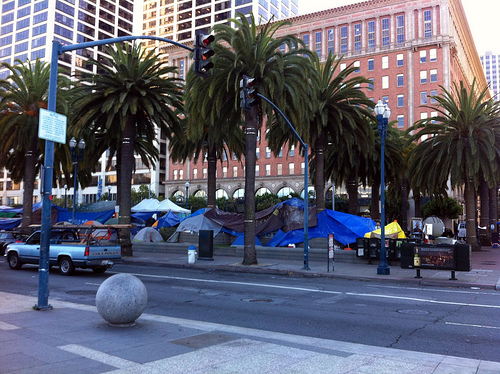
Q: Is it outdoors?
A: Yes, it is outdoors.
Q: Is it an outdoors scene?
A: Yes, it is outdoors.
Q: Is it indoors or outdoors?
A: It is outdoors.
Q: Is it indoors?
A: No, it is outdoors.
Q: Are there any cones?
A: No, there are no cones.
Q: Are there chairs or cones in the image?
A: No, there are no cones or chairs.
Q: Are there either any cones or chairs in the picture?
A: No, there are no cones or chairs.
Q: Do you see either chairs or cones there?
A: No, there are no cones or chairs.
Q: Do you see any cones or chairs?
A: No, there are no cones or chairs.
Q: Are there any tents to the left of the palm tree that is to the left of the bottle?
A: Yes, there are tents to the left of the palm tree.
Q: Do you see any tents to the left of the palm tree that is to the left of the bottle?
A: Yes, there are tents to the left of the palm tree.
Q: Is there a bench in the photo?
A: No, there are no benches.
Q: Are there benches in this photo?
A: No, there are no benches.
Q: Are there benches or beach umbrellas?
A: No, there are no benches or beach umbrellas.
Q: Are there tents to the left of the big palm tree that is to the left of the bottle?
A: Yes, there are tents to the left of the palm tree.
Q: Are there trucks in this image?
A: Yes, there is a truck.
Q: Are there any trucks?
A: Yes, there is a truck.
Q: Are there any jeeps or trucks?
A: Yes, there is a truck.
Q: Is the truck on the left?
A: Yes, the truck is on the left of the image.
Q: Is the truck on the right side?
A: No, the truck is on the left of the image.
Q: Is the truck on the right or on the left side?
A: The truck is on the left of the image.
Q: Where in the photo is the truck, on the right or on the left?
A: The truck is on the left of the image.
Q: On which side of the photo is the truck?
A: The truck is on the left of the image.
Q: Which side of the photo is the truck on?
A: The truck is on the left of the image.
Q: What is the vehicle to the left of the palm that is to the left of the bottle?
A: The vehicle is a truck.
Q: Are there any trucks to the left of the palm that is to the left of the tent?
A: Yes, there is a truck to the left of the palm tree.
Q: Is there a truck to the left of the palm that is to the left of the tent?
A: Yes, there is a truck to the left of the palm tree.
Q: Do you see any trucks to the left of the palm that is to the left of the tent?
A: Yes, there is a truck to the left of the palm tree.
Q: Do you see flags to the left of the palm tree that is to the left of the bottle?
A: No, there is a truck to the left of the palm.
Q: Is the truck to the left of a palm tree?
A: Yes, the truck is to the left of a palm tree.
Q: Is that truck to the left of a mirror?
A: No, the truck is to the left of a palm tree.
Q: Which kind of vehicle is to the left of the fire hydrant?
A: The vehicle is a truck.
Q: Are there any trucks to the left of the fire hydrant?
A: Yes, there is a truck to the left of the fire hydrant.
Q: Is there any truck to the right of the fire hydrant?
A: No, the truck is to the left of the fire hydrant.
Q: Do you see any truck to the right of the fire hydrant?
A: No, the truck is to the left of the fire hydrant.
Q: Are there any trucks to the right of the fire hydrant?
A: No, the truck is to the left of the fire hydrant.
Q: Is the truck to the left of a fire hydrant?
A: Yes, the truck is to the left of a fire hydrant.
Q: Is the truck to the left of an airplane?
A: No, the truck is to the left of a fire hydrant.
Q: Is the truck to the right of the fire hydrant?
A: No, the truck is to the left of the fire hydrant.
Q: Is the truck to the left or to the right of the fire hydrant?
A: The truck is to the left of the fire hydrant.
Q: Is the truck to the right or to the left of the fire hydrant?
A: The truck is to the left of the fire hydrant.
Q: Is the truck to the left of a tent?
A: Yes, the truck is to the left of a tent.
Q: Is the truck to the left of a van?
A: No, the truck is to the left of a tent.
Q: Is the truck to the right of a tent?
A: No, the truck is to the left of a tent.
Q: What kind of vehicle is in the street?
A: The vehicle is a truck.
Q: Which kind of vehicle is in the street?
A: The vehicle is a truck.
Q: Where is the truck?
A: The truck is in the street.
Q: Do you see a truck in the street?
A: Yes, there is a truck in the street.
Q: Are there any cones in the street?
A: No, there is a truck in the street.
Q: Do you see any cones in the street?
A: No, there is a truck in the street.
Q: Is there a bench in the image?
A: No, there are no benches.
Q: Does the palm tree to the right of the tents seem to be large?
A: Yes, the palm is large.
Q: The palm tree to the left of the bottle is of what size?
A: The palm is large.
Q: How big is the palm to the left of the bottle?
A: The palm tree is large.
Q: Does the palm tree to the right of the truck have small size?
A: No, the palm tree is large.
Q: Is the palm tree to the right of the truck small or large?
A: The palm is large.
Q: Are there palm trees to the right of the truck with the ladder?
A: Yes, there is a palm tree to the right of the truck.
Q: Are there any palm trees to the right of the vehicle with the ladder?
A: Yes, there is a palm tree to the right of the truck.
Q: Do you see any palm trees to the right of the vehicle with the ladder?
A: Yes, there is a palm tree to the right of the truck.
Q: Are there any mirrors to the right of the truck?
A: No, there is a palm tree to the right of the truck.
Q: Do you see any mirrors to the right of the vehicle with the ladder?
A: No, there is a palm tree to the right of the truck.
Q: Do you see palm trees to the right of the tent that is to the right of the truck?
A: Yes, there is a palm tree to the right of the tent.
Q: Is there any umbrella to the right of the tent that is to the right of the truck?
A: No, there is a palm tree to the right of the tent.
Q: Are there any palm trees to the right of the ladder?
A: Yes, there is a palm tree to the right of the ladder.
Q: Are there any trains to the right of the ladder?
A: No, there is a palm tree to the right of the ladder.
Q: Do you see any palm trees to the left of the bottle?
A: Yes, there is a palm tree to the left of the bottle.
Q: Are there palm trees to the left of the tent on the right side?
A: Yes, there is a palm tree to the left of the tent.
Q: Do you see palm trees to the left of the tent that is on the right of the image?
A: Yes, there is a palm tree to the left of the tent.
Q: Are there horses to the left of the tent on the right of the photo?
A: No, there is a palm tree to the left of the tent.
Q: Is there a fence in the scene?
A: No, there are no fences.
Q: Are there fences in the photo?
A: No, there are no fences.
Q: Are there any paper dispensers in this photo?
A: No, there are no paper dispensers.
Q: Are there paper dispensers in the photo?
A: No, there are no paper dispensers.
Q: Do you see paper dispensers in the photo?
A: No, there are no paper dispensers.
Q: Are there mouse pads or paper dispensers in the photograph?
A: No, there are no paper dispensers or mouse pads.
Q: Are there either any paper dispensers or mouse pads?
A: No, there are no paper dispensers or mouse pads.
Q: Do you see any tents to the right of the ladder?
A: Yes, there is a tent to the right of the ladder.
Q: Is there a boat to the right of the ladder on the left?
A: No, there is a tent to the right of the ladder.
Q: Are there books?
A: No, there are no books.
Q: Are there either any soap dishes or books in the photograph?
A: No, there are no books or soap dishes.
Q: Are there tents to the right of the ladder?
A: Yes, there is a tent to the right of the ladder.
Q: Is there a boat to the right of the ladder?
A: No, there is a tent to the right of the ladder.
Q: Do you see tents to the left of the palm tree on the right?
A: Yes, there is a tent to the left of the palm.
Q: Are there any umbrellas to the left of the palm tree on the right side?
A: No, there is a tent to the left of the palm.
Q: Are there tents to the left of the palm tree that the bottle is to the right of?
A: Yes, there is a tent to the left of the palm tree.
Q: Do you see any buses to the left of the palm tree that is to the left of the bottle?
A: No, there is a tent to the left of the palm tree.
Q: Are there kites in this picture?
A: No, there are no kites.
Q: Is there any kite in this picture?
A: No, there are no kites.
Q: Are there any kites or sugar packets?
A: No, there are no kites or sugar packets.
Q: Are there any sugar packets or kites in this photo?
A: No, there are no kites or sugar packets.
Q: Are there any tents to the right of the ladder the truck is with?
A: Yes, there is a tent to the right of the ladder.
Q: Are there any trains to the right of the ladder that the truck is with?
A: No, there is a tent to the right of the ladder.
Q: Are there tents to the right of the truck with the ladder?
A: Yes, there is a tent to the right of the truck.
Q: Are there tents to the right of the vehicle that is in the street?
A: Yes, there is a tent to the right of the truck.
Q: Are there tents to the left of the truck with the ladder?
A: No, the tent is to the right of the truck.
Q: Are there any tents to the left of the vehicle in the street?
A: No, the tent is to the right of the truck.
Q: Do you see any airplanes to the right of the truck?
A: No, there is a tent to the right of the truck.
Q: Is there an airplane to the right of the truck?
A: No, there is a tent to the right of the truck.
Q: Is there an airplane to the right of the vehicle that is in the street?
A: No, there is a tent to the right of the truck.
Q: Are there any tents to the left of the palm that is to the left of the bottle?
A: Yes, there is a tent to the left of the palm tree.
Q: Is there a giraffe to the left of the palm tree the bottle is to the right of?
A: No, there is a tent to the left of the palm.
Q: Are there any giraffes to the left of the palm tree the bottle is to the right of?
A: No, there is a tent to the left of the palm.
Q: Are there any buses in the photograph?
A: No, there are no buses.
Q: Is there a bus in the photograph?
A: No, there are no buses.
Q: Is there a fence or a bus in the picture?
A: No, there are no buses or fences.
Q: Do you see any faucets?
A: No, there are no faucets.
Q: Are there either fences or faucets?
A: No, there are no faucets or fences.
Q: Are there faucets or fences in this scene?
A: No, there are no faucets or fences.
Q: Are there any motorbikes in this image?
A: No, there are no motorbikes.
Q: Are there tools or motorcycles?
A: No, there are no motorcycles or tools.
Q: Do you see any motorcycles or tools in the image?
A: No, there are no motorcycles or tools.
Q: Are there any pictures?
A: No, there are no pictures.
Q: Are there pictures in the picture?
A: No, there are no pictures.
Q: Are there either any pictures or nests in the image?
A: No, there are no pictures or nests.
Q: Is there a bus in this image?
A: No, there are no buses.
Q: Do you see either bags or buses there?
A: No, there are no buses or bags.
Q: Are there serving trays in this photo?
A: No, there are no serving trays.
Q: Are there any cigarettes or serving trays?
A: No, there are no serving trays or cigarettes.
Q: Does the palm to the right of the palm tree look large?
A: Yes, the palm is large.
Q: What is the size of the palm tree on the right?
A: The palm tree is large.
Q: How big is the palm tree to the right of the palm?
A: The palm tree is large.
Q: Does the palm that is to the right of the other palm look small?
A: No, the palm is large.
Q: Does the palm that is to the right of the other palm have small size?
A: No, the palm is large.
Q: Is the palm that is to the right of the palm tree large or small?
A: The palm tree is large.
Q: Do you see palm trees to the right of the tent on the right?
A: Yes, there is a palm tree to the right of the tent.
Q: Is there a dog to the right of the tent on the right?
A: No, there is a palm tree to the right of the tent.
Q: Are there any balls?
A: Yes, there is a ball.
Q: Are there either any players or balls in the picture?
A: Yes, there is a ball.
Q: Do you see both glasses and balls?
A: No, there is a ball but no glasses.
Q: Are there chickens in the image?
A: No, there are no chickens.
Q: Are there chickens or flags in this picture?
A: No, there are no chickens or flags.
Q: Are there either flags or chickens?
A: No, there are no chickens or flags.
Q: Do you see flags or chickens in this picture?
A: No, there are no chickens or flags.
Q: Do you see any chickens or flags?
A: No, there are no chickens or flags.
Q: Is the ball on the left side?
A: Yes, the ball is on the left of the image.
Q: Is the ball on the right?
A: No, the ball is on the left of the image.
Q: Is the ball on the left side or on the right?
A: The ball is on the left of the image.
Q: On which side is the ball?
A: The ball is on the left of the image.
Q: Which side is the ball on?
A: The ball is on the left of the image.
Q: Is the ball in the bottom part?
A: Yes, the ball is in the bottom of the image.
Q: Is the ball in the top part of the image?
A: No, the ball is in the bottom of the image.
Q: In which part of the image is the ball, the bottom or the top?
A: The ball is in the bottom of the image.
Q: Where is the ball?
A: The ball is on the sidewalk.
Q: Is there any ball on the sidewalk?
A: Yes, there is a ball on the sidewalk.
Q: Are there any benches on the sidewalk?
A: No, there is a ball on the sidewalk.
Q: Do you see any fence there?
A: No, there are no fences.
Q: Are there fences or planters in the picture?
A: No, there are no fences or planters.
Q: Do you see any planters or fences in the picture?
A: No, there are no fences or planters.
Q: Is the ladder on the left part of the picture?
A: Yes, the ladder is on the left of the image.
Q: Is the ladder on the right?
A: No, the ladder is on the left of the image.